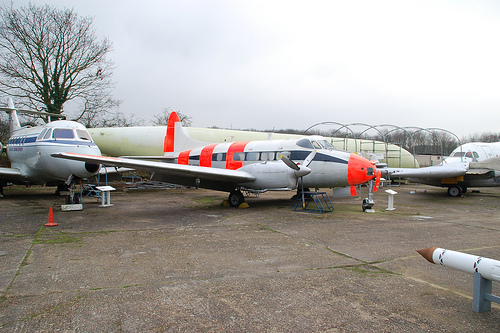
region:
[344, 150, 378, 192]
Orange nose of airplane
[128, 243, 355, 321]
Concrete ground below airplanes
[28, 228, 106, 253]
Grass growing between the cracks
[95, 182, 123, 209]
Step stool on ground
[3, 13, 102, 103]
Tall tree that is bare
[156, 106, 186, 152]
Orange and white tail of plane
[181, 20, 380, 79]
Cloudy grey sky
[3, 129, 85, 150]
Blue stripe on plane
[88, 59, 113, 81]
dead leaves in tree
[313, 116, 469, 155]
Metal object for planes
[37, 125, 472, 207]
Planes on the pavement.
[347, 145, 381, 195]
The plane has orange paint.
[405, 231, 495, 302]
A missle on the ground.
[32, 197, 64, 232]
A orange cone on ground.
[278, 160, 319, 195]
The propeller on the plane wing.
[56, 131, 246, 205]
The wing of the plane.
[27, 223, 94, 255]
Green grass on the pavement.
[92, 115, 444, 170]
A big plane behind the gate.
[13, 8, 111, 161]
A tree behind the plane.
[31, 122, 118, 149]
The cockpit of the plane.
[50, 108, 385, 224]
red and white airplane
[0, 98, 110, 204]
white and blue airplane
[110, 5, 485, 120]
grey overcast sky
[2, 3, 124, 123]
tree bare of leaves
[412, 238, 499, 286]
white missile shaped object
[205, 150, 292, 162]
windows on side of plane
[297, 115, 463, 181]
frame of plane hangar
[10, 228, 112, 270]
weeds growing in concrete cracks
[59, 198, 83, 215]
cinderblock under plane stand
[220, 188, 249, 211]
wheel with yellow wedges around it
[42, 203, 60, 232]
an orange safety cone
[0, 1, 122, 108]
a tree missing all of its leaves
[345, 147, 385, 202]
nose of a plane painted bright orange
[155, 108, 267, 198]
orange stripes painted on a plane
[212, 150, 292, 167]
windows of a small passenger plane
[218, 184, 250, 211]
landing wheel secured by blocks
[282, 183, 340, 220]
small blue stepladder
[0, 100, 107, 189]
white plane with blue stripe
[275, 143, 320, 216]
wing propeller for a passenger plane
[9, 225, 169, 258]
moss growing in the cracks of the cement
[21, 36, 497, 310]
airplanes on the ground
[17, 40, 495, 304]
planes on the ground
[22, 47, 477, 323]
airplanes parked on the ground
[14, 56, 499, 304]
planes parked on the ground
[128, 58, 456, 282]
a plane with orange stripes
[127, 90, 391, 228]
an airplane with orange stripes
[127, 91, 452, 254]
orange striped airplane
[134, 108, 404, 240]
an orange striped plane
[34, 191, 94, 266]
an orange cone on the ground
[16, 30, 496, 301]
an area with planes